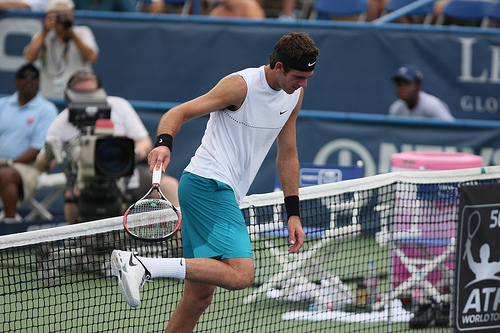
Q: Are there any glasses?
A: No, there are no glasses.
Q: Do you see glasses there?
A: No, there are no glasses.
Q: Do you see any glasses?
A: No, there are no glasses.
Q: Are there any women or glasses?
A: No, there are no glasses or women.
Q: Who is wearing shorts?
A: The man is wearing shorts.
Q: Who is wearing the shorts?
A: The man is wearing shorts.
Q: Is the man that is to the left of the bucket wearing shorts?
A: Yes, the man is wearing shorts.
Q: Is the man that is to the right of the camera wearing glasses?
A: No, the man is wearing shorts.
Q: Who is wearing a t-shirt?
A: The man is wearing a t-shirt.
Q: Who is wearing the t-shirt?
A: The man is wearing a t-shirt.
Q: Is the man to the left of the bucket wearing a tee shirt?
A: Yes, the man is wearing a tee shirt.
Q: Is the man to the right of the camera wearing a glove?
A: No, the man is wearing a tee shirt.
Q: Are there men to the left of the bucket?
A: Yes, there is a man to the left of the bucket.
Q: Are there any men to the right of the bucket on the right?
A: No, the man is to the left of the bucket.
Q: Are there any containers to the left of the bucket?
A: No, there is a man to the left of the bucket.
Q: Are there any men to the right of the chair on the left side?
A: Yes, there is a man to the right of the chair.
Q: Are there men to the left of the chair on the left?
A: No, the man is to the right of the chair.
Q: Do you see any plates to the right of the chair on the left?
A: No, there is a man to the right of the chair.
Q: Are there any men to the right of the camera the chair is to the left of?
A: Yes, there is a man to the right of the camera.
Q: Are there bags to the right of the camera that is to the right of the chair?
A: No, there is a man to the right of the camera.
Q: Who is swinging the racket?
A: The man is swinging the racket.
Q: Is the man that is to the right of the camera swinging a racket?
A: Yes, the man is swinging a racket.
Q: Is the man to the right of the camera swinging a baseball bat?
A: No, the man is swinging a racket.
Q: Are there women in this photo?
A: No, there are no women.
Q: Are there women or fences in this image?
A: No, there are no women or fences.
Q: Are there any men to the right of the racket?
A: No, the man is to the left of the racket.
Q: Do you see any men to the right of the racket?
A: No, the man is to the left of the racket.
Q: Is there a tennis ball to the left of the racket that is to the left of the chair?
A: No, there is a man to the left of the tennis racket.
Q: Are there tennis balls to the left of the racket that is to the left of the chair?
A: No, there is a man to the left of the tennis racket.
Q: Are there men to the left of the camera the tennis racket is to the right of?
A: Yes, there is a man to the left of the camera.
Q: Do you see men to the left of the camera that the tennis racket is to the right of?
A: Yes, there is a man to the left of the camera.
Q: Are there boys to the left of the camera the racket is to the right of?
A: No, there is a man to the left of the camera.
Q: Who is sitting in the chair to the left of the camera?
A: The man is sitting in the chair.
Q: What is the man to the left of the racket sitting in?
A: The man is sitting in the chair.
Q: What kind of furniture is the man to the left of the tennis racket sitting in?
A: The man is sitting in the chair.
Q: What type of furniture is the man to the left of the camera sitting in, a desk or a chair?
A: The man is sitting in a chair.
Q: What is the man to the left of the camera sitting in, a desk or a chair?
A: The man is sitting in a chair.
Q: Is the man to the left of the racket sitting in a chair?
A: Yes, the man is sitting in a chair.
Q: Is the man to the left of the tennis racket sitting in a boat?
A: No, the man is sitting in a chair.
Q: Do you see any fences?
A: No, there are no fences.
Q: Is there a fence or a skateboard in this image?
A: No, there are no fences or skateboards.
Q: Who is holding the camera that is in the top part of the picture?
A: The man is holding the camera.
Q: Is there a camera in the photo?
A: Yes, there is a camera.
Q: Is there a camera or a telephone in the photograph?
A: Yes, there is a camera.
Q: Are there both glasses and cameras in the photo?
A: No, there is a camera but no glasses.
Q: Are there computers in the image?
A: No, there are no computers.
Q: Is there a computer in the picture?
A: No, there are no computers.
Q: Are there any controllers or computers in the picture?
A: No, there are no computers or controllers.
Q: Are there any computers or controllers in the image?
A: No, there are no computers or controllers.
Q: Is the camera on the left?
A: Yes, the camera is on the left of the image.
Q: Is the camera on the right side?
A: No, the camera is on the left of the image.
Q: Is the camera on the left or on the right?
A: The camera is on the left of the image.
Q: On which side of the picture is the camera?
A: The camera is on the left of the image.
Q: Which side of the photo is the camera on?
A: The camera is on the left of the image.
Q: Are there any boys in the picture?
A: No, there are no boys.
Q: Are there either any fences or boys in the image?
A: No, there are no boys or fences.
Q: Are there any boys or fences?
A: No, there are no boys or fences.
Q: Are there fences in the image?
A: No, there are no fences.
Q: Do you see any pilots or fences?
A: No, there are no fences or pilots.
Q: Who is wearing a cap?
A: The man is wearing a cap.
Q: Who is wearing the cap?
A: The man is wearing a cap.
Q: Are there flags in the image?
A: Yes, there is a flag.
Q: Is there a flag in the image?
A: Yes, there is a flag.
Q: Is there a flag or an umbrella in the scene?
A: Yes, there is a flag.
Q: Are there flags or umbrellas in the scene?
A: Yes, there is a flag.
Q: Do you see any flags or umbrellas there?
A: Yes, there is a flag.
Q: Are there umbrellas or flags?
A: Yes, there is a flag.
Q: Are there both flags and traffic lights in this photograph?
A: No, there is a flag but no traffic lights.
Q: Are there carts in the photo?
A: No, there are no carts.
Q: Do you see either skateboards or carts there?
A: No, there are no carts or skateboards.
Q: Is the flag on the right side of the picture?
A: Yes, the flag is on the right of the image.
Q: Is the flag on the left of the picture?
A: No, the flag is on the right of the image.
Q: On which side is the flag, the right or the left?
A: The flag is on the right of the image.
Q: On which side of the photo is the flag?
A: The flag is on the right of the image.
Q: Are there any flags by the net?
A: Yes, there is a flag by the net.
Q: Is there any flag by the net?
A: Yes, there is a flag by the net.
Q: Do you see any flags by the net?
A: Yes, there is a flag by the net.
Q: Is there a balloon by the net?
A: No, there is a flag by the net.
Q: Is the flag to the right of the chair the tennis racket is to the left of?
A: Yes, the flag is to the right of the chair.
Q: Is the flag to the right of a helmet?
A: No, the flag is to the right of the chair.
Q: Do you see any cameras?
A: Yes, there is a camera.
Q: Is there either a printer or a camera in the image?
A: Yes, there is a camera.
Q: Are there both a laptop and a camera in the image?
A: No, there is a camera but no laptops.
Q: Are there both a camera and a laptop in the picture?
A: No, there is a camera but no laptops.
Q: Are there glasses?
A: No, there are no glasses.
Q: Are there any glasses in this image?
A: No, there are no glasses.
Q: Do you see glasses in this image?
A: No, there are no glasses.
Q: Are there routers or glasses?
A: No, there are no glasses or routers.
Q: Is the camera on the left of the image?
A: Yes, the camera is on the left of the image.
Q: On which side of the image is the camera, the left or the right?
A: The camera is on the left of the image.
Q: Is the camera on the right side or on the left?
A: The camera is on the left of the image.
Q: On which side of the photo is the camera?
A: The camera is on the left of the image.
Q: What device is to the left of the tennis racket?
A: The device is a camera.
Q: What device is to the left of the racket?
A: The device is a camera.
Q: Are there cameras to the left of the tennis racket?
A: Yes, there is a camera to the left of the tennis racket.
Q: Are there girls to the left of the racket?
A: No, there is a camera to the left of the racket.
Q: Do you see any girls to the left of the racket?
A: No, there is a camera to the left of the racket.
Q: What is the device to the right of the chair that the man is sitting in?
A: The device is a camera.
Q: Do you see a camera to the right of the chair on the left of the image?
A: Yes, there is a camera to the right of the chair.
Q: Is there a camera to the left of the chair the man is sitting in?
A: No, the camera is to the right of the chair.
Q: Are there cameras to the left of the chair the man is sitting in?
A: No, the camera is to the right of the chair.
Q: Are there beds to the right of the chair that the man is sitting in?
A: No, there is a camera to the right of the chair.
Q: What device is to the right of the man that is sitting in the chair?
A: The device is a camera.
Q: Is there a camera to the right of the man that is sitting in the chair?
A: Yes, there is a camera to the right of the man.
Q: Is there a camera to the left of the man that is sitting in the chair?
A: No, the camera is to the right of the man.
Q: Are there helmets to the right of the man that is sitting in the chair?
A: No, there is a camera to the right of the man.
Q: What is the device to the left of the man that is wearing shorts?
A: The device is a camera.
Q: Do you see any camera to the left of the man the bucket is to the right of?
A: Yes, there is a camera to the left of the man.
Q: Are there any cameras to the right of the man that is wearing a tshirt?
A: No, the camera is to the left of the man.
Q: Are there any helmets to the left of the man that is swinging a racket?
A: No, there is a camera to the left of the man.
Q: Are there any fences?
A: No, there are no fences.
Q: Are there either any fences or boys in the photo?
A: No, there are no fences or boys.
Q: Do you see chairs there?
A: Yes, there is a chair.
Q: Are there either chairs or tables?
A: Yes, there is a chair.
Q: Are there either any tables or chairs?
A: Yes, there is a chair.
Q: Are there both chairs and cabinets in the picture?
A: No, there is a chair but no cabinets.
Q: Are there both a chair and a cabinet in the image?
A: No, there is a chair but no cabinets.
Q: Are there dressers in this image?
A: No, there are no dressers.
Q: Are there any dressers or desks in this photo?
A: No, there are no dressers or desks.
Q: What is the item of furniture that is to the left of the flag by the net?
A: The piece of furniture is a chair.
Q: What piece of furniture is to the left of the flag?
A: The piece of furniture is a chair.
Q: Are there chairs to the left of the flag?
A: Yes, there is a chair to the left of the flag.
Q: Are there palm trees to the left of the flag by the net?
A: No, there is a chair to the left of the flag.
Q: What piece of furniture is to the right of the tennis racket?
A: The piece of furniture is a chair.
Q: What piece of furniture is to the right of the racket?
A: The piece of furniture is a chair.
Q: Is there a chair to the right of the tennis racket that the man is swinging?
A: Yes, there is a chair to the right of the racket.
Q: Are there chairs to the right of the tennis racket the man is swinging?
A: Yes, there is a chair to the right of the racket.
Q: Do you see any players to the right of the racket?
A: No, there is a chair to the right of the racket.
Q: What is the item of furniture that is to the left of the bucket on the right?
A: The piece of furniture is a chair.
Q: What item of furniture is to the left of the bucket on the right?
A: The piece of furniture is a chair.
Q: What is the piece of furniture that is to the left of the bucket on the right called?
A: The piece of furniture is a chair.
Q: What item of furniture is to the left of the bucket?
A: The piece of furniture is a chair.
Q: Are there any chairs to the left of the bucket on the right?
A: Yes, there is a chair to the left of the bucket.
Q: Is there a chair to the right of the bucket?
A: No, the chair is to the left of the bucket.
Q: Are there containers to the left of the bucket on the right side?
A: No, there is a chair to the left of the bucket.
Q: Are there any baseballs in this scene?
A: No, there are no baseballs.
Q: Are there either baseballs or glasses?
A: No, there are no baseballs or glasses.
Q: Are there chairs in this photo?
A: Yes, there is a chair.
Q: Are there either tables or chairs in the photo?
A: Yes, there is a chair.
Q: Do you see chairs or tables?
A: Yes, there is a chair.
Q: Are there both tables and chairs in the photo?
A: No, there is a chair but no tables.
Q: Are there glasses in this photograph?
A: No, there are no glasses.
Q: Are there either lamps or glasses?
A: No, there are no glasses or lamps.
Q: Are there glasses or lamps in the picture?
A: No, there are no glasses or lamps.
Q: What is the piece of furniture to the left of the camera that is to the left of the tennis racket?
A: The piece of furniture is a chair.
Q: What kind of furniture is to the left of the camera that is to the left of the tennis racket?
A: The piece of furniture is a chair.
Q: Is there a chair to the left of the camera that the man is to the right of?
A: Yes, there is a chair to the left of the camera.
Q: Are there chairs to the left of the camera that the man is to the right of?
A: Yes, there is a chair to the left of the camera.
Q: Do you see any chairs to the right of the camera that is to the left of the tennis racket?
A: No, the chair is to the left of the camera.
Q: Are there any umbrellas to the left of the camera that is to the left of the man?
A: No, there is a chair to the left of the camera.